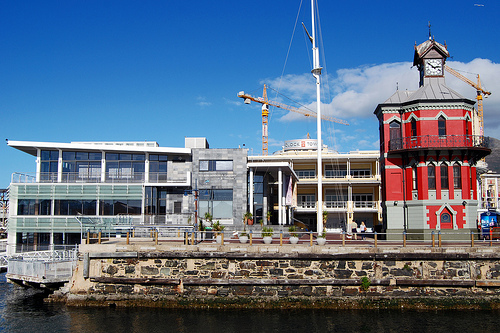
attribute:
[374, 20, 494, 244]
building — red, grey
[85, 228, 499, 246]
fence — wood, metal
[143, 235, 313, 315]
wall — brick, retaining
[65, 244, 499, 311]
wall — brown, brick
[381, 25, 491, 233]
building — red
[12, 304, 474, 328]
water — dark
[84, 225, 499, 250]
fencing — brown, protective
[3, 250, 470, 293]
wall — stone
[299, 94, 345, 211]
metal pole — white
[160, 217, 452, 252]
fence — stone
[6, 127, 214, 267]
building — white, green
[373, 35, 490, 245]
clocktower — red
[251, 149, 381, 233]
building — tan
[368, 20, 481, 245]
building — tan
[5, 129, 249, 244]
building — tan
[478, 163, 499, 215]
building — tan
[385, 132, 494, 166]
observation deck — rounded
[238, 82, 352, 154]
crane — tall, yellow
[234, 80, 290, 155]
crane — tall, yellow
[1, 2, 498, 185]
sky — clear, blue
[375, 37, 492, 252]
building — red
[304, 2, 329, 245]
pole — tall, white, flag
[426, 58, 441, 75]
face — white, black, clock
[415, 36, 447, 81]
clock — white, black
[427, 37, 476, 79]
clock — grey, metal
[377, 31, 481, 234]
building — red, painted